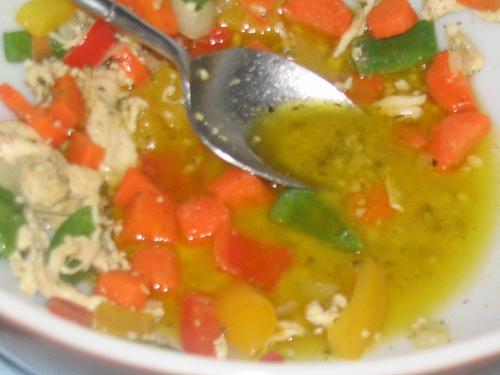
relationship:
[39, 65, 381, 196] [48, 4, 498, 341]
spoon with soup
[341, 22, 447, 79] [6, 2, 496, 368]
peppers in soup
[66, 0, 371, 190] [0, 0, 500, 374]
spoon in bowl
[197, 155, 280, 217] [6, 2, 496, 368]
carrot in soup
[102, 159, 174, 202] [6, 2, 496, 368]
carrot in soup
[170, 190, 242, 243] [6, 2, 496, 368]
carrot in soup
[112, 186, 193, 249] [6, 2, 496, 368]
carrot in soup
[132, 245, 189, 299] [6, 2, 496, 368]
carrot in soup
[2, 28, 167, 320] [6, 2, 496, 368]
meat in soup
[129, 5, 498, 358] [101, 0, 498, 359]
broth of broth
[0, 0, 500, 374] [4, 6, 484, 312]
bowl of soup